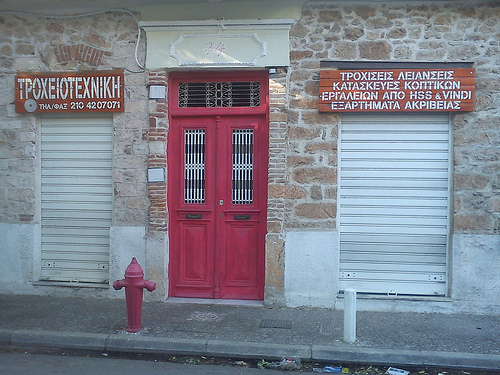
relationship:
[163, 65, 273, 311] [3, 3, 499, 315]
door on front of building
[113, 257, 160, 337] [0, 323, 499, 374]
fire hydrant along curb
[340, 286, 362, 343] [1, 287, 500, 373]
pole on sidewalk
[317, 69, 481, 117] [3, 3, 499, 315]
sign on building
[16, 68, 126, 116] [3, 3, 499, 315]
sign on building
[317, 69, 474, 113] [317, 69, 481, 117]
sign on sign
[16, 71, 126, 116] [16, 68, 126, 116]
sign on sign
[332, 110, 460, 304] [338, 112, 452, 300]
window has metal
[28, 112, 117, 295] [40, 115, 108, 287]
window has metal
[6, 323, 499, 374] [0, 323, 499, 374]
curb by curb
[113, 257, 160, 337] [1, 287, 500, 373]
fire hydrant on sidewalk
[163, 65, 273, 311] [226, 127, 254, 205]
door has blind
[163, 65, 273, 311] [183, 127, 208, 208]
door has blind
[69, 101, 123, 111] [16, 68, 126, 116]
phone number on sign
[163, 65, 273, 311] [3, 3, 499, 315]
door on building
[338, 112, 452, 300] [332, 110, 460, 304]
metal on window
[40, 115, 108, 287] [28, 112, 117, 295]
metal on window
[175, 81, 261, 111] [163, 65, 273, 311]
window above door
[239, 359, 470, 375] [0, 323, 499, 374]
trash in curb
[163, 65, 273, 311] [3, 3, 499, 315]
door of building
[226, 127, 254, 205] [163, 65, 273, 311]
blind on door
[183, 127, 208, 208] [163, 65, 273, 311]
blind on door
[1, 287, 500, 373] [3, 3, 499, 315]
sidewalk in front of building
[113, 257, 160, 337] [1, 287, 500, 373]
fire hydrant sitting on sidewalk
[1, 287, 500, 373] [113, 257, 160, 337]
sidewalk has a fire hydrant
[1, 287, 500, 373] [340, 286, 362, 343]
sidewalk has a pole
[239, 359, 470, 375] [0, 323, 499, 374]
trash on side of curb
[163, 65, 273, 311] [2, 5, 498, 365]
door in greece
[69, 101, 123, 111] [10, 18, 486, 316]
phone number on business